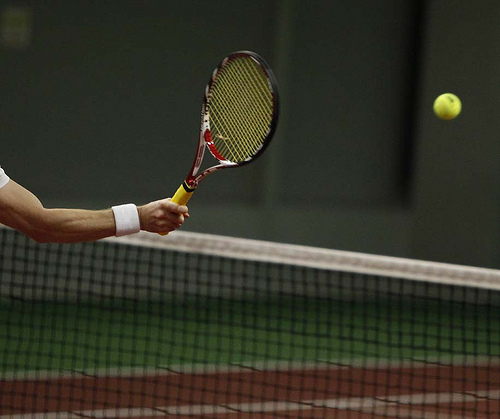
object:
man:
[0, 171, 189, 243]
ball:
[433, 94, 462, 119]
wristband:
[111, 202, 140, 237]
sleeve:
[0, 166, 14, 194]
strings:
[210, 59, 273, 159]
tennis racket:
[169, 47, 283, 208]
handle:
[172, 179, 195, 206]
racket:
[171, 48, 282, 203]